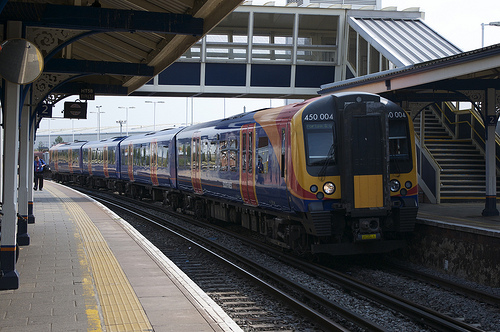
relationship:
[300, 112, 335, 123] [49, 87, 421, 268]
number 450 004 written on train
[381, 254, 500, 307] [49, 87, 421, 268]
rail of train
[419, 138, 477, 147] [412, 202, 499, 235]
stair coming down to platform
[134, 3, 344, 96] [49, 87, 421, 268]
catwalk platform built over train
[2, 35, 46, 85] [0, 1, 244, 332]
mirror hanging on platform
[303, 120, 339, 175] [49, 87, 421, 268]
windshield of train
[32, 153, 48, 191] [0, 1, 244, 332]
man walking on platform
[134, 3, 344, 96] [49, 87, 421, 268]
catwalk platform hanging over a train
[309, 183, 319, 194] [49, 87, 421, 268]
right headlight on front of a train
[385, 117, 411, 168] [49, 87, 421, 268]
windshield of a train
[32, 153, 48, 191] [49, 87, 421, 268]
man standing near a train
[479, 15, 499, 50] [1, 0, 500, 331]
light near a train station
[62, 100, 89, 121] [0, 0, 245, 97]
sign hanging from ceiling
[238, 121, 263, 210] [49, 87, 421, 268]
door on side of a train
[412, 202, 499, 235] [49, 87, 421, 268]
platform near a train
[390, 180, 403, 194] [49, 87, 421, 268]
headlight of a train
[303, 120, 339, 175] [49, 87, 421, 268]
windshield of a train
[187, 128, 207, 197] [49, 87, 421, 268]
door of a train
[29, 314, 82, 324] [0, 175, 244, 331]
brick placed in ground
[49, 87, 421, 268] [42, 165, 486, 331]
train on top of train track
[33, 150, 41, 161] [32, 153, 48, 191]
head of a man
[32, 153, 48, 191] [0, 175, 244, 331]
man walking on ground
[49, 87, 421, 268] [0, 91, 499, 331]
train riding in foreground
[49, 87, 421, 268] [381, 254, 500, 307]
train on top of rail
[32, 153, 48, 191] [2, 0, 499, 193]
man standing in background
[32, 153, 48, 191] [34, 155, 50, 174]
man wearing a shirt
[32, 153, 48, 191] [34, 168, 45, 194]
man wearing pants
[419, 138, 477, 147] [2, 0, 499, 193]
stair pictured in background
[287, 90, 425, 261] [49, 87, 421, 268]
end part of train